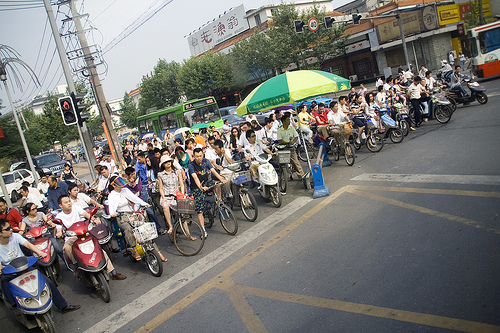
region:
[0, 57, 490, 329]
A very large group of cyclists and motorcyclists.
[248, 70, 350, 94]
The green and yellow top of an umbrella.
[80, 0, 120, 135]
An electric pole.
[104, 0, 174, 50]
Wires hanging from an electric pole.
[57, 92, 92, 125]
A red light from a traffic light.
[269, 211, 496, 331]
The middle of the road.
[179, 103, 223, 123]
Green bus with yellow lights.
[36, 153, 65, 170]
A black jeep behind the crowd of cyclists.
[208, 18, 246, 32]
Chinese scriptures in a white banner.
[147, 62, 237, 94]
Green trees in the left sidewalk.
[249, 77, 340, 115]
Green and yellow umbrella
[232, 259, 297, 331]
Yellow lines on road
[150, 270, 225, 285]
White markings on road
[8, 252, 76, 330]
Blue and silver scooter on end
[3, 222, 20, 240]
Sunglasses on person's face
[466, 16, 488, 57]
Red and white bus in background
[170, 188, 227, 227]
Basket on front of bike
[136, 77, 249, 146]
Bright green bus in background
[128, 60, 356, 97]
Trees lining road near buildings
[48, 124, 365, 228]
Many people on bikes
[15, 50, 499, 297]
A crowd of people on bikes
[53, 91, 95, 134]
Black traffic light is in the background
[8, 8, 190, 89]
The sky is powder blue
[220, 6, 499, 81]
Small building are in the background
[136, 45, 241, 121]
Trees are in the background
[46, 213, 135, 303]
Bike is bright Red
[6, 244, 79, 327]
The bike is blue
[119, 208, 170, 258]
Bike has a white basket in the front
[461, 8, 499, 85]
Bus is in the background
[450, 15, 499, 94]
Bus's color is white and red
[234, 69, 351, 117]
Green and yellow umbrella.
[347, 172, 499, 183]
Thick white line on the road.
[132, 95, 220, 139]
Green bus behind the people.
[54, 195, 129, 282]
Man sitting on red motorbike.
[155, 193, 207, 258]
Bicycle with a basket on front.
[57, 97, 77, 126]
Crosswalk device on pole.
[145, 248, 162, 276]
Small front wheel of a scooter.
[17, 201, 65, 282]
Woman on a motorbike.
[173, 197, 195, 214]
Basket on the front of a bicycle.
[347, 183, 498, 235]
Orange lines on the road.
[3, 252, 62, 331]
blue and silver colored motorbike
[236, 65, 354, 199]
green and yellow umbrella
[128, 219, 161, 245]
white basket on a bicycle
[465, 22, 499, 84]
back end of a red and white bus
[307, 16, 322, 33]
a sign with the number 40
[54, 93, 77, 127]
red light on a traffic signal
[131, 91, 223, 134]
a green bus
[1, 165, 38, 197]
white car with a black stripe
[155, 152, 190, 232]
woman with a white hat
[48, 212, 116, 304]
red colored motorbike